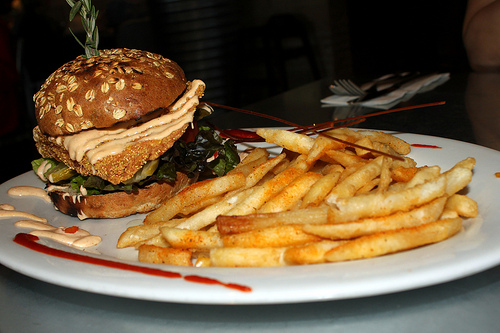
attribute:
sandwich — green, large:
[27, 45, 231, 221]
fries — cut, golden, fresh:
[118, 130, 476, 263]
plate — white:
[0, 126, 499, 304]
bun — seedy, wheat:
[31, 47, 189, 137]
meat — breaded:
[34, 79, 209, 186]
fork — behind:
[337, 74, 405, 98]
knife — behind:
[347, 69, 435, 107]